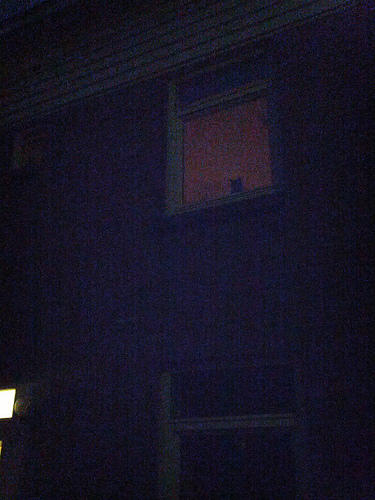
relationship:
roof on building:
[1, 0, 373, 124] [2, 1, 375, 494]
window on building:
[173, 48, 281, 205] [2, 1, 375, 494]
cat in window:
[229, 176, 247, 194] [173, 48, 281, 205]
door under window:
[165, 359, 312, 499] [173, 48, 281, 205]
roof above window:
[1, 0, 373, 124] [173, 48, 281, 205]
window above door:
[173, 48, 281, 205] [165, 359, 312, 499]